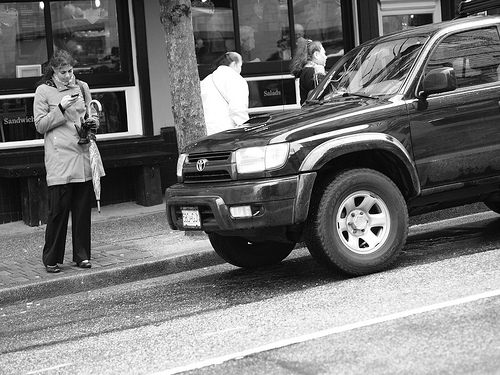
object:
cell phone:
[69, 89, 84, 103]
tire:
[312, 165, 409, 276]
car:
[162, 32, 500, 275]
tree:
[162, 0, 208, 244]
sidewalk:
[0, 193, 255, 290]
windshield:
[309, 36, 426, 99]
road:
[2, 200, 496, 364]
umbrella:
[78, 92, 113, 216]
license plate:
[178, 204, 201, 224]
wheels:
[309, 161, 411, 281]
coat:
[30, 78, 110, 185]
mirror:
[417, 63, 451, 97]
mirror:
[307, 90, 312, 100]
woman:
[35, 55, 103, 270]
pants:
[45, 183, 95, 262]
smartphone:
[70, 89, 80, 104]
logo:
[190, 154, 209, 174]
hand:
[73, 114, 100, 137]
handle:
[88, 96, 104, 123]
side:
[408, 12, 492, 193]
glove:
[71, 114, 100, 148]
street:
[0, 204, 498, 370]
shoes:
[42, 258, 63, 273]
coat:
[293, 62, 327, 101]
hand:
[58, 87, 80, 113]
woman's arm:
[78, 85, 105, 132]